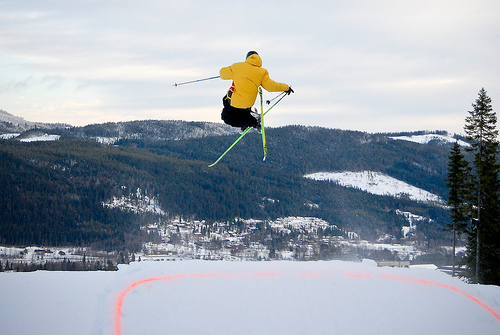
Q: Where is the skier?
A: Mid Air.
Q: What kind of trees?
A: Pine.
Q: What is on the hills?
A: Snow.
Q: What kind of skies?
A: Cloudy.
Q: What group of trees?
A: Pine.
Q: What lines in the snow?
A: Orange.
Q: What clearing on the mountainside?
A: White.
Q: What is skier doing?
A: Jumping.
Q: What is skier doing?
A: Trick.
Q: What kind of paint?
A: Orange.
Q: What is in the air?
A: Person with green ski's.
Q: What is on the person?
A: Yellow jacket.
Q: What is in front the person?
A: Forest on mountain.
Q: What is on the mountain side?
A: Patch of snow.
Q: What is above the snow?
A: Person in air.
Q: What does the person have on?
A: Ski gear.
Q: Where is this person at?
A: Up in mountains.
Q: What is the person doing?
A: Enjoying winter.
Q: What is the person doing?
A: Enjoying view.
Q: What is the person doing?
A: Skier is jumping.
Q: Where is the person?
A: In the air.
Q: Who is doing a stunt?
A: The skier.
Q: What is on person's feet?
A: The skis.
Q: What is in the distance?
A: Mountains.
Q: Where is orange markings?
A: On the snow.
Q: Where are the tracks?
A: In the snow.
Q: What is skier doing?
A: Performing a trick.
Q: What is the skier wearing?
A: Yellow parka.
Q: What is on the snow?
A: Bright paint.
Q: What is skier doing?
A: Jumping.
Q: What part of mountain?
A: Ridge.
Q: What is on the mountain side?
A: Trees.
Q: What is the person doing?
A: Skiing.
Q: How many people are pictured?
A: One.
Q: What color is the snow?
A: White.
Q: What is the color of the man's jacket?
A: Yellow.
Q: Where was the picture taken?
A: A ski resort.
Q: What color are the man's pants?
A: Black.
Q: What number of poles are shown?
A: Two.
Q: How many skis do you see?
A: Two.